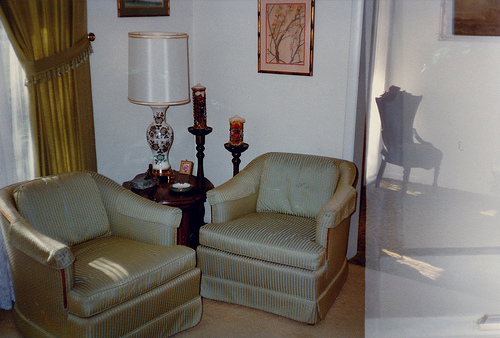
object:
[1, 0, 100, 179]
curtains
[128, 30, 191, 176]
lamp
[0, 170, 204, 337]
chair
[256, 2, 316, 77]
pink art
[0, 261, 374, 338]
carpet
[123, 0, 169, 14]
picture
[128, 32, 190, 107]
lampshade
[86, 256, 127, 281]
sunlight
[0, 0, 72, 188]
window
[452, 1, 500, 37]
image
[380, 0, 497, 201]
wall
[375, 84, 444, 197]
chair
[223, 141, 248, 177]
stand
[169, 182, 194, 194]
ashtray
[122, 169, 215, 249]
side table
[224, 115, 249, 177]
candle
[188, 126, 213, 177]
stand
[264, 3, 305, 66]
picture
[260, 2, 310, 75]
image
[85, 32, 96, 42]
fastener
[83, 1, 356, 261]
wall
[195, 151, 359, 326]
chair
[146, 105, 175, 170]
floral pattern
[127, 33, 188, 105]
white shade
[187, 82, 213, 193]
candle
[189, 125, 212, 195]
pillar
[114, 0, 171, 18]
art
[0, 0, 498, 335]
room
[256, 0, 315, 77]
frame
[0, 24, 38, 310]
sheer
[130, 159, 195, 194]
items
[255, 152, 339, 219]
fabric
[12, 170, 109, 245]
fabric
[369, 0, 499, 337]
background